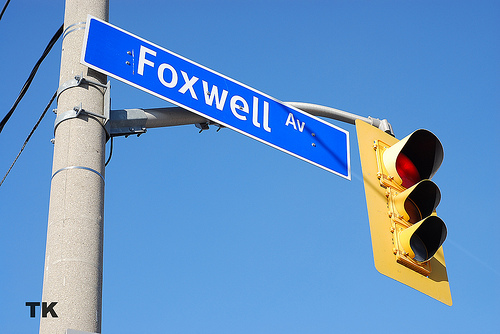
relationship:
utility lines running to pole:
[2, 92, 55, 189] [40, 3, 108, 333]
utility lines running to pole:
[0, 0, 63, 184] [40, 3, 108, 333]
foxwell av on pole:
[78, 13, 351, 183] [45, 108, 115, 287]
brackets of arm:
[49, 75, 111, 144] [108, 98, 395, 138]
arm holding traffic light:
[108, 98, 395, 138] [355, 119, 451, 305]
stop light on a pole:
[351, 116, 451, 306] [111, 100, 397, 137]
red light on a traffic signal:
[380, 130, 444, 187] [352, 120, 453, 305]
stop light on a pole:
[351, 116, 451, 306] [98, 68, 372, 155]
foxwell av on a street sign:
[81, 14, 408, 183] [80, 13, 352, 179]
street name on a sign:
[135, 42, 304, 132] [73, 15, 389, 180]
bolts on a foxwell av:
[118, 49, 136, 67] [78, 13, 351, 183]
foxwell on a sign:
[137, 43, 271, 134] [3, 0, 338, 180]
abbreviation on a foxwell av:
[284, 112, 306, 133] [78, 13, 351, 183]